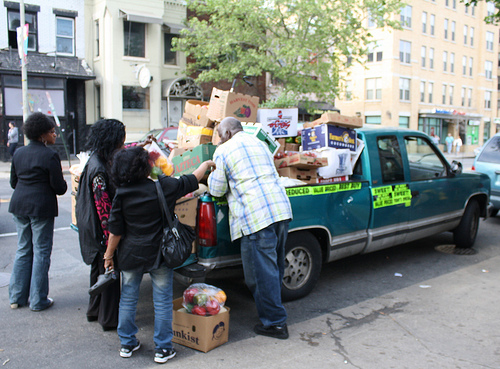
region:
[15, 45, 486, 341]
truck parked on city street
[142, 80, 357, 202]
cardboard boxes piled high on truck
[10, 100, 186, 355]
women looking at the produce available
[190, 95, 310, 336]
man in plaid shirt leaning over truck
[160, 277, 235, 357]
produce box with plastic bag of colorful vegetables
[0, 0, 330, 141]
narrow buildings across the street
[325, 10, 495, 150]
large tan building with many windows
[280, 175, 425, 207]
black print on yellow strips across truck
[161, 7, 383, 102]
large and airy tree in front of building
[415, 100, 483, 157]
people standing in front of building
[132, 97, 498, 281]
a blue pick up truck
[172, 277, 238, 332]
a bag of produce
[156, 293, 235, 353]
a brown cardboard box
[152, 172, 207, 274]
a black leather purse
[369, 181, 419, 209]
some neon green stickers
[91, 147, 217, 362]
a woman holding a shoe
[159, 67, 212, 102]
a small building awning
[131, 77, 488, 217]
a truck full of boxes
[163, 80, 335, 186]
a bunch of boxes of food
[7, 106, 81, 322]
a woman with an aphro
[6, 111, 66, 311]
lady checking items in the truck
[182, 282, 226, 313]
bag of vegetables near the truck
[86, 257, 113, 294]
sandles being held by person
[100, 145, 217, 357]
lady getting mans attention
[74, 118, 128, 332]
lady shopping for vegetables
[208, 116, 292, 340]
man selling vegetables from his truck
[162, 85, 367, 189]
cargo loaded in bed of the truck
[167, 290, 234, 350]
box of vegetables on the street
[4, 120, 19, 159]
individual walking across the street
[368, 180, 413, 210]
stickers on side of the truck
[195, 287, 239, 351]
A box is visible.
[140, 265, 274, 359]
A box is visible.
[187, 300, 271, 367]
A box is visible.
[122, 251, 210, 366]
A box is visible.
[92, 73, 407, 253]
A bunch of boxes in the back of truck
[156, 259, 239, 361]
Box containing colorful vegetables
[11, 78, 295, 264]
Talking about the cargo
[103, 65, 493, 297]
Blue-green pickup truck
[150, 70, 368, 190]
Empty boxes in the back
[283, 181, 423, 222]
Flourescent green advertisement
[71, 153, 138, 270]
Sleeveless black jacket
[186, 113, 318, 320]
Plaid jacket and blue jeans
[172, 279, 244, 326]
Red, yellow and green bell peppers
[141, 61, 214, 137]
Canopy over entrance